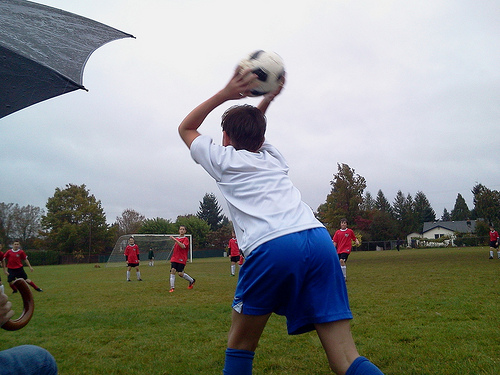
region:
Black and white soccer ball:
[238, 47, 288, 98]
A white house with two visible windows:
[407, 221, 474, 244]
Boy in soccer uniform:
[168, 224, 196, 292]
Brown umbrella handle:
[11, 276, 36, 326]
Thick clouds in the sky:
[330, 75, 498, 158]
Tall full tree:
[42, 183, 105, 260]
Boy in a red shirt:
[119, 234, 144, 283]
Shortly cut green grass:
[392, 268, 499, 373]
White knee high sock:
[168, 272, 174, 290]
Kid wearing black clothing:
[146, 243, 155, 266]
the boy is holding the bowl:
[186, 41, 389, 357]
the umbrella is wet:
[10, 4, 127, 126]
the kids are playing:
[97, 200, 392, 302]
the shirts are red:
[83, 225, 233, 280]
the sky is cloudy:
[118, 35, 224, 272]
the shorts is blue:
[240, 213, 385, 373]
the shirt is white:
[178, 133, 360, 223]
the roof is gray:
[377, 194, 492, 241]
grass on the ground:
[351, 256, 477, 367]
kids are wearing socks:
[88, 252, 281, 294]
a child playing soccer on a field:
[2, 238, 41, 293]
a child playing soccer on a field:
[123, 235, 145, 284]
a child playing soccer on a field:
[168, 223, 197, 288]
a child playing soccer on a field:
[222, 230, 244, 276]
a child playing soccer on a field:
[332, 215, 361, 278]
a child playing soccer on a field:
[485, 224, 499, 262]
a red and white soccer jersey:
[122, 241, 142, 265]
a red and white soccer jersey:
[170, 234, 190, 264]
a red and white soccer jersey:
[227, 238, 242, 258]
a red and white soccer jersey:
[332, 228, 357, 255]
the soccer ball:
[241, 50, 282, 94]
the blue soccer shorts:
[235, 225, 351, 332]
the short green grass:
[372, 263, 482, 350]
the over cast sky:
[302, 10, 497, 157]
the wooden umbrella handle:
[2, 277, 34, 334]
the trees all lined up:
[1, 177, 490, 239]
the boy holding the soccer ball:
[177, 47, 374, 373]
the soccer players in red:
[4, 225, 496, 265]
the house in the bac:
[407, 218, 493, 244]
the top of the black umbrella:
[3, 0, 134, 118]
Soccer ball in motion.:
[233, 47, 287, 96]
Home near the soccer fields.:
[405, 217, 486, 247]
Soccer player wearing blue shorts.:
[232, 225, 349, 327]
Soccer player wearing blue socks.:
[218, 349, 383, 374]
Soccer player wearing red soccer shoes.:
[167, 280, 199, 295]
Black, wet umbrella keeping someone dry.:
[0, 0, 137, 122]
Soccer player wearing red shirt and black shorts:
[122, 233, 143, 281]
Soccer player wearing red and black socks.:
[27, 277, 44, 297]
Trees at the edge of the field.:
[6, 180, 112, 264]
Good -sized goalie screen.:
[112, 232, 195, 270]